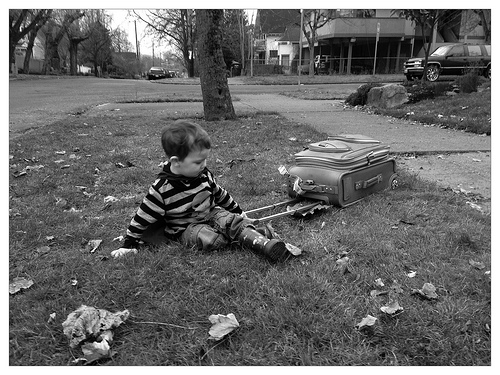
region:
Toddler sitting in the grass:
[107, 117, 288, 262]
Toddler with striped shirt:
[110, 125, 285, 260]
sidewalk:
[237, 91, 487, 214]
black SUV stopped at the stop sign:
[402, 41, 487, 82]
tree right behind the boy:
[195, 10, 235, 120]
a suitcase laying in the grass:
[235, 130, 395, 220]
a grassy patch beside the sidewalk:
[10, 110, 495, 365]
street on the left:
[1, 76, 152, 134]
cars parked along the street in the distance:
[148, 66, 173, 77]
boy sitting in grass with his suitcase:
[111, 121, 399, 263]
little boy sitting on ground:
[85, 96, 290, 263]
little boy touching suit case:
[115, 94, 406, 266]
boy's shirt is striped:
[117, 166, 265, 248]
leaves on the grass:
[15, 91, 485, 353]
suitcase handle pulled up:
[240, 186, 317, 233]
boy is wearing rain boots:
[203, 214, 300, 269]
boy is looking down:
[117, 111, 288, 263]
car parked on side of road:
[397, 38, 497, 90]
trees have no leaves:
[8, 10, 255, 60]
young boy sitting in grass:
[110, 108, 411, 278]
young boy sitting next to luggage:
[111, 108, 438, 278]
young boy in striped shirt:
[101, 113, 288, 287]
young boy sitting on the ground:
[116, 115, 301, 282]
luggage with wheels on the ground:
[245, 119, 416, 223]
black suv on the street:
[397, 31, 490, 86]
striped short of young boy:
[116, 169, 256, 231]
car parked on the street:
[147, 63, 167, 83]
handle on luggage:
[357, 172, 387, 191]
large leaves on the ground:
[58, 286, 148, 364]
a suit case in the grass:
[255, 128, 402, 230]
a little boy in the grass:
[103, 118, 300, 280]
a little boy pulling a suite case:
[97, 120, 407, 276]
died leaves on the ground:
[60, 291, 432, 366]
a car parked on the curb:
[397, 38, 492, 87]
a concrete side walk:
[236, 83, 303, 111]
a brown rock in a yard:
[368, 81, 409, 105]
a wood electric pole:
[133, 13, 140, 70]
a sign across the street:
[369, 19, 384, 75]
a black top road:
[36, 71, 117, 98]